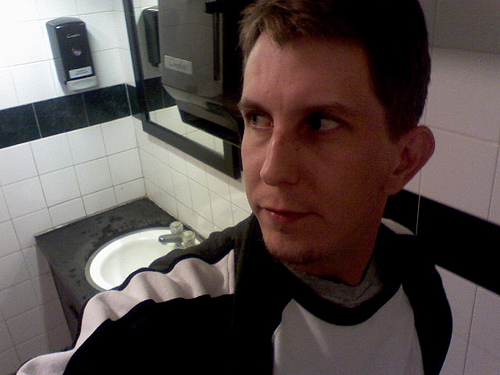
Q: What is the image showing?
A: It is showing a bathroom.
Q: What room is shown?
A: It is a bathroom.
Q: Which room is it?
A: It is a bathroom.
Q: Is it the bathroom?
A: Yes, it is the bathroom.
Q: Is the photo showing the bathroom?
A: Yes, it is showing the bathroom.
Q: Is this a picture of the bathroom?
A: Yes, it is showing the bathroom.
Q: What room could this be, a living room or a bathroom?
A: It is a bathroom.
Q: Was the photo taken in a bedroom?
A: No, the picture was taken in a bathroom.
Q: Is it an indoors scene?
A: Yes, it is indoors.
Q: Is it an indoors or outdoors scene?
A: It is indoors.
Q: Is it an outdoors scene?
A: No, it is indoors.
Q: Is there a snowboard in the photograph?
A: No, there are no snowboards.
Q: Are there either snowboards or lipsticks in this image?
A: No, there are no snowboards or lipsticks.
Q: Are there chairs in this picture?
A: No, there are no chairs.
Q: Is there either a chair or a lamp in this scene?
A: No, there are no chairs or lamps.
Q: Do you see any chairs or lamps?
A: No, there are no chairs or lamps.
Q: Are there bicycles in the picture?
A: No, there are no bicycles.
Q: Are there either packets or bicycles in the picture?
A: No, there are no bicycles or packets.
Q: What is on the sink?
A: The water is on the sink.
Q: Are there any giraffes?
A: No, there are no giraffes.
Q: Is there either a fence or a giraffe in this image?
A: No, there are no giraffes or fences.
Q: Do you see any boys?
A: No, there are no boys.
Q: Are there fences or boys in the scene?
A: No, there are no boys or fences.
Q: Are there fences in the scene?
A: No, there are no fences.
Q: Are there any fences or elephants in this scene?
A: No, there are no fences or elephants.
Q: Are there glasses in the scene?
A: No, there are no glasses.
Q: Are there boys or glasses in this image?
A: No, there are no glasses or boys.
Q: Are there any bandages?
A: No, there are no bandages.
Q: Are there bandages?
A: No, there are no bandages.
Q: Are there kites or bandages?
A: No, there are no bandages or kites.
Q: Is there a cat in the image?
A: No, there are no cats.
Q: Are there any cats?
A: No, there are no cats.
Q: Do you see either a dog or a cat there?
A: No, there are no cats or dogs.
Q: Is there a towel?
A: No, there are no towels.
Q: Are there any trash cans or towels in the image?
A: No, there are no towels or trash cans.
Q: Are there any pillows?
A: No, there are no pillows.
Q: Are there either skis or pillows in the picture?
A: No, there are no pillows or skis.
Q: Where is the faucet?
A: The faucet is in the bathroom.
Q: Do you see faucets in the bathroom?
A: Yes, there is a faucet in the bathroom.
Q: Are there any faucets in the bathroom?
A: Yes, there is a faucet in the bathroom.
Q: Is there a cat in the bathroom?
A: No, there is a faucet in the bathroom.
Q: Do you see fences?
A: No, there are no fences.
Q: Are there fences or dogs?
A: No, there are no fences or dogs.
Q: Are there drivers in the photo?
A: No, there are no drivers.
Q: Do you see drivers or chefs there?
A: No, there are no drivers or chefs.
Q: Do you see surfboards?
A: No, there are no surfboards.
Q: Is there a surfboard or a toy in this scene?
A: No, there are no surfboards or toys.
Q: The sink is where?
A: The sink is in the bathroom.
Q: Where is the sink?
A: The sink is in the bathroom.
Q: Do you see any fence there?
A: No, there are no fences.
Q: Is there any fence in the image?
A: No, there are no fences.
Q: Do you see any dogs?
A: No, there are no dogs.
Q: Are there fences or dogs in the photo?
A: No, there are no dogs or fences.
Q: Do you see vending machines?
A: No, there are no vending machines.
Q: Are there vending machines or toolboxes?
A: No, there are no vending machines or toolboxes.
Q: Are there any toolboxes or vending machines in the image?
A: No, there are no vending machines or toolboxes.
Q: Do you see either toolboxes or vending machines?
A: No, there are no vending machines or toolboxes.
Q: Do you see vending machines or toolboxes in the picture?
A: No, there are no vending machines or toolboxes.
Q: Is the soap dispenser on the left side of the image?
A: Yes, the soap dispenser is on the left of the image.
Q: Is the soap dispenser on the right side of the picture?
A: No, the soap dispenser is on the left of the image.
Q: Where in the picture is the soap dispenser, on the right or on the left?
A: The soap dispenser is on the left of the image.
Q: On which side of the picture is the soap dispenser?
A: The soap dispenser is on the left of the image.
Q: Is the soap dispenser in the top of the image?
A: Yes, the soap dispenser is in the top of the image.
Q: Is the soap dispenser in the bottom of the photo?
A: No, the soap dispenser is in the top of the image.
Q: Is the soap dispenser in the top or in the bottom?
A: The soap dispenser is in the top of the image.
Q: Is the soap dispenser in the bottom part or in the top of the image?
A: The soap dispenser is in the top of the image.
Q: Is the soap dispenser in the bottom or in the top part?
A: The soap dispenser is in the top of the image.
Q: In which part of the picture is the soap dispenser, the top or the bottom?
A: The soap dispenser is in the top of the image.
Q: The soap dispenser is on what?
A: The soap dispenser is on the wall.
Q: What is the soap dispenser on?
A: The soap dispenser is on the wall.